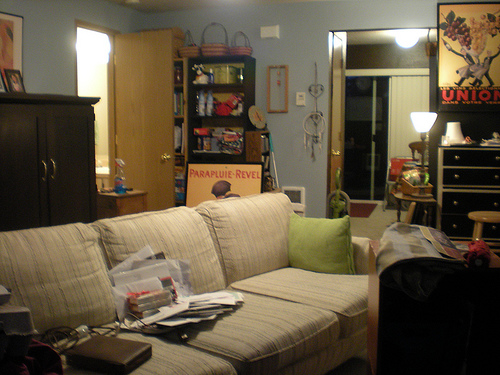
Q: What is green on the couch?
A: Pillow.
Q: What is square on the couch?
A: Pillow.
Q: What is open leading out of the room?
A: Door.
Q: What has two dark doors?
A: Dresser.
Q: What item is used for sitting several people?
A: A sofa.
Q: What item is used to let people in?
A: A door.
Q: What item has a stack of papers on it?
A: A sofa.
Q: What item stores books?
A: A book shelf.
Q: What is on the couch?
A: Some documents.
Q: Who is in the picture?
A: No one.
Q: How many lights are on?
A: 3.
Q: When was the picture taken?
A: Night.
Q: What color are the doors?
A: Beige.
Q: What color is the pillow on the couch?
A: Green.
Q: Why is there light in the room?
A: It is at night.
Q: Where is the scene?
A: In the living room.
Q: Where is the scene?
A: Living room.